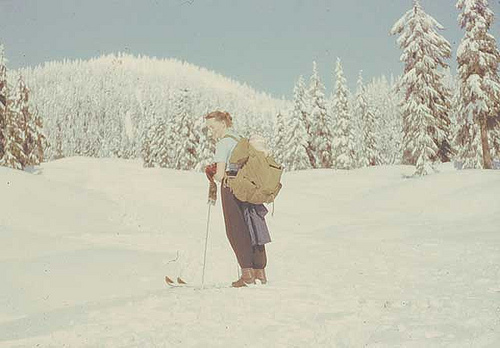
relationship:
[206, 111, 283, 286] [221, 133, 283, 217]
person has backpack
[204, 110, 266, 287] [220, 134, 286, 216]
person has bag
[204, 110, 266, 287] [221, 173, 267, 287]
person has pants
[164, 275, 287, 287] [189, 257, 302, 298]
skii in snow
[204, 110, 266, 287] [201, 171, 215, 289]
person has ski pole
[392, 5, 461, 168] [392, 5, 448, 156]
tree has snow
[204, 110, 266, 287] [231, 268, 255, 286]
person has boot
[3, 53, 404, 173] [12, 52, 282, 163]
mountain has trees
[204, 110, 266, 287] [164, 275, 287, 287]
person has skii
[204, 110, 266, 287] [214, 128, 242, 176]
person wearing shirt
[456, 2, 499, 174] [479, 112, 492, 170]
tree has trunk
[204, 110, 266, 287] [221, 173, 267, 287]
person wearing pants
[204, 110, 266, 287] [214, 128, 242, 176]
person has shirt